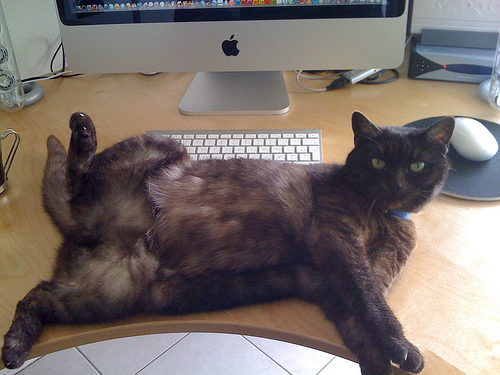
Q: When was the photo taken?
A: Day time.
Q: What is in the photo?
A: Cat.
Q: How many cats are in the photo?
A: 1.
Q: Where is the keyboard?
A: Behind the cat.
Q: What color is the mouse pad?
A: Black.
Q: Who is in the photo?
A: No one.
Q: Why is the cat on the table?
A: Relaxing.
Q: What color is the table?
A: Brown.